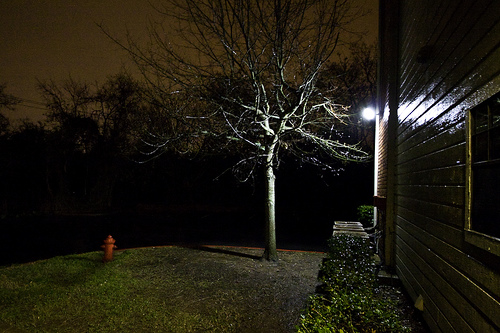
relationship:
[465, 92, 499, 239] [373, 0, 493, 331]
window on side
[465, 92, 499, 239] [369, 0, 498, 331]
window on house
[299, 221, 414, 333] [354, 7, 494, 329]
bushes in front of building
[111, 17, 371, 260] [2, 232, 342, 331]
tree in yard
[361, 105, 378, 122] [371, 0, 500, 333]
light shining on building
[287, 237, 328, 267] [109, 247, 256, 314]
line in ground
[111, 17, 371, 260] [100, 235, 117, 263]
tree right of fire hydrant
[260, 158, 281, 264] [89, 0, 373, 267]
trunk of tree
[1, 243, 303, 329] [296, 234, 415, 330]
grass in front shrubs